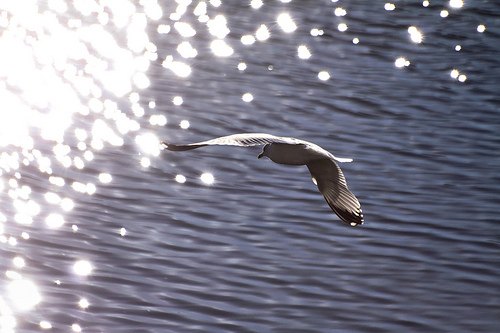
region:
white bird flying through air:
[156, 123, 411, 240]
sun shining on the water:
[17, 76, 114, 197]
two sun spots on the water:
[171, 169, 222, 186]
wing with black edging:
[301, 147, 371, 235]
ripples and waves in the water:
[379, 129, 459, 302]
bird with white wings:
[143, 107, 413, 253]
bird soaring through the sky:
[149, 121, 407, 256]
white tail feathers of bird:
[333, 147, 367, 167]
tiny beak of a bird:
[254, 147, 266, 161]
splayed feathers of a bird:
[158, 132, 270, 164]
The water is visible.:
[177, 246, 249, 315]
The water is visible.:
[228, 263, 269, 327]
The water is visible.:
[245, 242, 407, 326]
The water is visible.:
[201, 251, 339, 330]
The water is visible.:
[283, 251, 371, 308]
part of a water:
[273, 70, 319, 115]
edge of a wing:
[342, 200, 371, 226]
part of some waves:
[239, 225, 277, 278]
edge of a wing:
[317, 166, 343, 236]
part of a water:
[220, 255, 269, 313]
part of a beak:
[250, 142, 267, 164]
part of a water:
[234, 240, 275, 292]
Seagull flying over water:
[131, 108, 440, 267]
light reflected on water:
[5, 6, 312, 303]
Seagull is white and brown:
[136, 111, 401, 242]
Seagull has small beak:
[156, 126, 392, 246]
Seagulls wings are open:
[148, 108, 395, 268]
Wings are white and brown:
[153, 108, 408, 265]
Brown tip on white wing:
[306, 159, 386, 249]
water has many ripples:
[73, 35, 483, 319]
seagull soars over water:
[105, 105, 437, 272]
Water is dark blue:
[21, 22, 499, 327]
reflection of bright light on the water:
[4, 4, 127, 141]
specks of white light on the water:
[264, 1, 479, 86]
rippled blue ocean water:
[391, 193, 481, 331]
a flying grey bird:
[207, 123, 374, 244]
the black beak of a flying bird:
[252, 145, 269, 164]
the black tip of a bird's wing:
[330, 196, 367, 236]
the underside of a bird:
[268, 146, 307, 168]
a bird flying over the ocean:
[13, 34, 496, 299]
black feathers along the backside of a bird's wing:
[240, 141, 290, 146]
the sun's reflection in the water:
[47, 43, 129, 134]